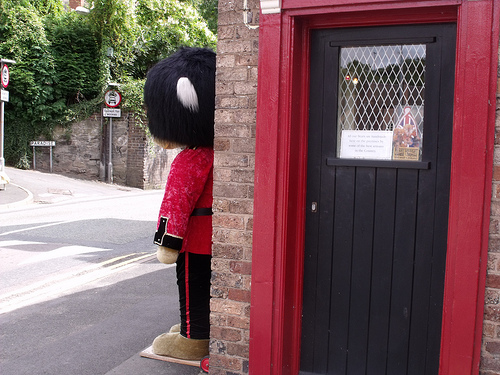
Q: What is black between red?
A: Door.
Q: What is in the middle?
A: Black door.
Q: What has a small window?
A: Door.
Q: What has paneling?
A: Black door.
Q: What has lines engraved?
A: Door.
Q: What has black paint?
A: Door.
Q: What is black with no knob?
A: Door.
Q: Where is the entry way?
A: Black door.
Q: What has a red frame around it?
A: Door.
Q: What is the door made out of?
A: Wood.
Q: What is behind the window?
A: A chain screen.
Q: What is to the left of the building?
A: A street.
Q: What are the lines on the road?
A: Traffic lines.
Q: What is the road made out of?
A: Pavement.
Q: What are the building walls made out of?
A: Brick.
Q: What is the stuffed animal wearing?
A: Foot Guard Uniform.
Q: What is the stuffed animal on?
A: A Handtruck.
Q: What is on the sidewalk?
A: A huge stuffed bear.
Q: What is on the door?
A: A window.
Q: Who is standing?
A: Guard.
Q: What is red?
A: Door frame.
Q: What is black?
A: Door.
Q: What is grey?
A: Road.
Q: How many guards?
A: One.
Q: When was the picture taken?
A: Daytime.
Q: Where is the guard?
A: To the left of the door.